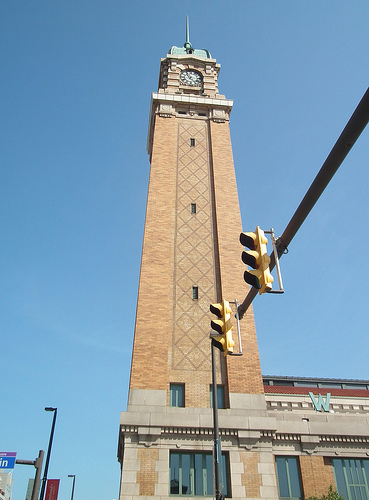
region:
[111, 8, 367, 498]
tall tower on building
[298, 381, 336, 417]
the letter W on building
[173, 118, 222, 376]
diamond pattern on side of tower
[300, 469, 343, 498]
greenery visible near side of building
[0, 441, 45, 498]
a blue and purple sign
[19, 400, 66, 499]
banners on a street light's pole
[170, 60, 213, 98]
clock on tower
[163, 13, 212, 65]
spire on top of tower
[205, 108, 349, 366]
yellow painted traffic lights on black pole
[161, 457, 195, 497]
reflection of nearby building in windows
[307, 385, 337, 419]
W on the building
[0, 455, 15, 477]
blue and white street sign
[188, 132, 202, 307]
three rectangle windows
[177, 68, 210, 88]
clock on the building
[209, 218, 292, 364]
two streetlights on a pole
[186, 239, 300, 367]
streetlights are yellow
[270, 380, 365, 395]
roof is red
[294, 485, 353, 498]
tree in front of building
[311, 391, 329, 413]
W is a light green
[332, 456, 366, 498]
window trim is green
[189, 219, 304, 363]
The stop lights are yellow.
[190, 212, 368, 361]
The stop lights are on the pole.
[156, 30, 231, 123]
The clock is high.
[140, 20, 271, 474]
The clock tower is tall.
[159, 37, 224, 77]
The roof is green.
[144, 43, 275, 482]
The building is tan.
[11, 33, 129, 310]
The sky is clear.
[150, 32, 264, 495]
The windows are small.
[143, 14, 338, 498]
The building is tall.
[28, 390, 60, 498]
The light is black.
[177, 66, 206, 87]
a round black clock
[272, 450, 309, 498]
a window on the building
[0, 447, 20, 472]
a blue and purple street sign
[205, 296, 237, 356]
a yellow bank of traffic lights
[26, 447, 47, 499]
a gray metal pole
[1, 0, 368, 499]
a clear blue sky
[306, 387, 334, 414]
a large letter on the building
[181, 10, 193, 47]
the spire of the clock tower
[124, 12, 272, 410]
a large brick clock tower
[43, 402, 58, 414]
a street light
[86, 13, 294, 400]
A very tall clock tower.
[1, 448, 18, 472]
Part of a red and blue sign.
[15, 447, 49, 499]
Grey support pole for sign.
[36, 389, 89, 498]
Two tall street lights.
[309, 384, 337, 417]
The letter W on side of building.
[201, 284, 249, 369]
A traffic light on the left.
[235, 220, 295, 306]
A traffic light on the right.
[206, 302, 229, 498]
Vertical support pole for traffic lights.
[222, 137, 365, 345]
Horizontal support pole for traffic lights.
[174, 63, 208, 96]
Round clock face at top of tower.